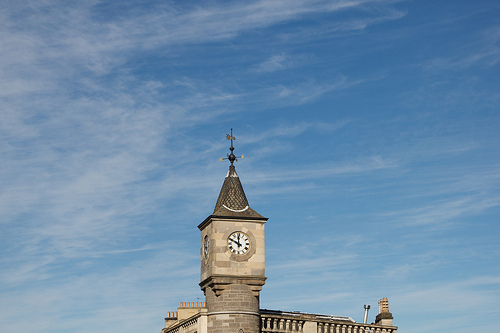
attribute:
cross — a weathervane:
[220, 127, 245, 171]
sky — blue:
[49, 17, 455, 176]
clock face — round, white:
[227, 230, 252, 257]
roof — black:
[193, 168, 271, 228]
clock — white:
[227, 231, 250, 253]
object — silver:
[338, 269, 398, 331]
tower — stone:
[196, 129, 268, 331]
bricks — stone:
[211, 258, 233, 268]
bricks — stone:
[212, 220, 231, 232]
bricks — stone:
[242, 220, 259, 234]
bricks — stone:
[247, 254, 266, 271]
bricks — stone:
[227, 281, 244, 293]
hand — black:
[234, 232, 243, 247]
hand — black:
[226, 232, 241, 246]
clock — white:
[225, 229, 252, 257]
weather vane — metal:
[218, 129, 242, 170]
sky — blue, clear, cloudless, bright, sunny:
[1, 0, 496, 331]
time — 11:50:
[226, 230, 256, 253]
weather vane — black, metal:
[217, 126, 249, 166]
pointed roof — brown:
[208, 167, 269, 218]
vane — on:
[192, 127, 314, 222]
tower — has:
[176, 130, 284, 327]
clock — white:
[221, 226, 254, 263]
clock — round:
[228, 231, 248, 254]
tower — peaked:
[197, 162, 269, 331]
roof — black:
[196, 164, 268, 230]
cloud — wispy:
[397, 183, 498, 231]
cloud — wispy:
[427, 50, 487, 80]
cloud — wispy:
[392, 271, 496, 316]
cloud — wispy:
[254, 43, 299, 78]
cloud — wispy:
[280, 224, 364, 272]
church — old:
[157, 126, 395, 329]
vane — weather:
[215, 121, 248, 166]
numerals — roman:
[231, 233, 249, 253]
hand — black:
[235, 232, 239, 251]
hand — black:
[225, 236, 238, 246]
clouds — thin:
[10, 11, 170, 228]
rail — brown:
[254, 312, 399, 330]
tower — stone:
[198, 210, 264, 330]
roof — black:
[210, 162, 260, 218]